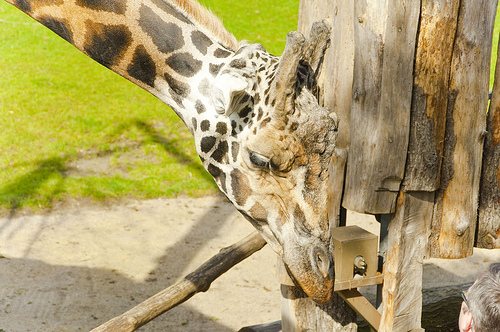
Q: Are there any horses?
A: No, there are no horses.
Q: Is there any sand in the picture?
A: Yes, there is sand.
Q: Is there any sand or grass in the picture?
A: Yes, there is sand.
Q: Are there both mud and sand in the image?
A: No, there is sand but no mud.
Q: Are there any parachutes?
A: No, there are no parachutes.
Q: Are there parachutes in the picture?
A: No, there are no parachutes.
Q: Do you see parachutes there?
A: No, there are no parachutes.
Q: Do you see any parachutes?
A: No, there are no parachutes.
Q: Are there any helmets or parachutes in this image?
A: No, there are no parachutes or helmets.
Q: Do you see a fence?
A: Yes, there is a fence.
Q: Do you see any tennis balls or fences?
A: Yes, there is a fence.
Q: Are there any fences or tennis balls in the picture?
A: Yes, there is a fence.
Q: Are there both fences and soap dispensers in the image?
A: No, there is a fence but no soap dispensers.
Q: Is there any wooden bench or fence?
A: Yes, there is a wood fence.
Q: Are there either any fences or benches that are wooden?
A: Yes, the fence is wooden.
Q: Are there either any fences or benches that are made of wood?
A: Yes, the fence is made of wood.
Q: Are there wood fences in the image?
A: Yes, there is a wood fence.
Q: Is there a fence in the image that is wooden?
A: Yes, there is a fence that is wooden.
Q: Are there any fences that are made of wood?
A: Yes, there is a fence that is made of wood.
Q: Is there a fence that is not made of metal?
A: Yes, there is a fence that is made of wood.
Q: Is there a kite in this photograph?
A: No, there are no kites.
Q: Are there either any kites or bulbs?
A: No, there are no kites or bulbs.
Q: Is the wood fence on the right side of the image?
A: Yes, the fence is on the right of the image.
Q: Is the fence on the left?
A: No, the fence is on the right of the image.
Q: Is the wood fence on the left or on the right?
A: The fence is on the right of the image.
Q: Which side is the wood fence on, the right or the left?
A: The fence is on the right of the image.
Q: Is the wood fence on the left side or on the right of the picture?
A: The fence is on the right of the image.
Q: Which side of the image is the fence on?
A: The fence is on the right of the image.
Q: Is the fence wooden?
A: Yes, the fence is wooden.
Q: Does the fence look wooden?
A: Yes, the fence is wooden.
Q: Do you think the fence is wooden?
A: Yes, the fence is wooden.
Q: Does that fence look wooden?
A: Yes, the fence is wooden.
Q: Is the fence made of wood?
A: Yes, the fence is made of wood.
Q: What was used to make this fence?
A: The fence is made of wood.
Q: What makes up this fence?
A: The fence is made of wood.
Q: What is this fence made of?
A: The fence is made of wood.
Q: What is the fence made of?
A: The fence is made of wood.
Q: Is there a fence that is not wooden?
A: No, there is a fence but it is wooden.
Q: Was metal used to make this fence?
A: No, the fence is made of wood.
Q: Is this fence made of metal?
A: No, the fence is made of wood.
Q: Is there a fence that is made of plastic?
A: No, there is a fence but it is made of wood.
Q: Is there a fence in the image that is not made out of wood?
A: No, there is a fence but it is made of wood.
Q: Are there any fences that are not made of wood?
A: No, there is a fence but it is made of wood.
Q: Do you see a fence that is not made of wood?
A: No, there is a fence but it is made of wood.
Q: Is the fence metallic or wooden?
A: The fence is wooden.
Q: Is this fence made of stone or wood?
A: The fence is made of wood.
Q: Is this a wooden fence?
A: Yes, this is a wooden fence.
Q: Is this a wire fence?
A: No, this is a wooden fence.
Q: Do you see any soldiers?
A: No, there are no soldiers.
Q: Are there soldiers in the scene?
A: No, there are no soldiers.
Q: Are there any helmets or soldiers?
A: No, there are no soldiers or helmets.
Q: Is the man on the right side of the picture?
A: Yes, the man is on the right of the image.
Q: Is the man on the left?
A: No, the man is on the right of the image.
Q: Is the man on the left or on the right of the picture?
A: The man is on the right of the image.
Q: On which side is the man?
A: The man is on the right of the image.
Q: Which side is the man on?
A: The man is on the right of the image.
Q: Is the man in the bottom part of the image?
A: Yes, the man is in the bottom of the image.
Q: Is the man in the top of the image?
A: No, the man is in the bottom of the image.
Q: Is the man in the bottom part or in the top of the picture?
A: The man is in the bottom of the image.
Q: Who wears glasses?
A: The man wears glasses.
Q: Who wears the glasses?
A: The man wears glasses.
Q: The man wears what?
A: The man wears glasses.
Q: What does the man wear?
A: The man wears glasses.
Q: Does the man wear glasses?
A: Yes, the man wears glasses.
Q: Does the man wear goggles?
A: No, the man wears glasses.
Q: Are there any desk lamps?
A: No, there are no desk lamps.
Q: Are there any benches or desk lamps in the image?
A: No, there are no desk lamps or benches.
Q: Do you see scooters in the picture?
A: No, there are no scooters.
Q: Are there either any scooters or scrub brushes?
A: No, there are no scooters or scrub brushes.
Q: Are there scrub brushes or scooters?
A: No, there are no scooters or scrub brushes.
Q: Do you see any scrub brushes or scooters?
A: No, there are no scooters or scrub brushes.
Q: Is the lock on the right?
A: Yes, the lock is on the right of the image.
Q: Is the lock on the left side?
A: No, the lock is on the right of the image.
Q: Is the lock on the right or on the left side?
A: The lock is on the right of the image.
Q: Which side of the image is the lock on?
A: The lock is on the right of the image.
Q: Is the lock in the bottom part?
A: Yes, the lock is in the bottom of the image.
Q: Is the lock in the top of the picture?
A: No, the lock is in the bottom of the image.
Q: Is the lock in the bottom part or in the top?
A: The lock is in the bottom of the image.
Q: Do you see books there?
A: No, there are no books.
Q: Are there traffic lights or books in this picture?
A: No, there are no books or traffic lights.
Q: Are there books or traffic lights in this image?
A: No, there are no books or traffic lights.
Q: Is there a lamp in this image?
A: No, there are no lamps.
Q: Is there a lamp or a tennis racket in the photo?
A: No, there are no lamps or rackets.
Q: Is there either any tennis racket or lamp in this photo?
A: No, there are no lamps or rackets.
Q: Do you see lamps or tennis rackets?
A: No, there are no lamps or tennis rackets.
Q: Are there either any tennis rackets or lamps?
A: No, there are no lamps or tennis rackets.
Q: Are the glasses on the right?
A: Yes, the glasses are on the right of the image.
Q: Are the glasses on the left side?
A: No, the glasses are on the right of the image.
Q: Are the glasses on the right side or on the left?
A: The glasses are on the right of the image.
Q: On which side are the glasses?
A: The glasses are on the right of the image.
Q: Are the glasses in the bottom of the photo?
A: Yes, the glasses are in the bottom of the image.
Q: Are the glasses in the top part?
A: No, the glasses are in the bottom of the image.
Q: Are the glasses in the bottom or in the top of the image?
A: The glasses are in the bottom of the image.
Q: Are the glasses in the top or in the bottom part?
A: The glasses are in the bottom of the image.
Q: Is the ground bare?
A: Yes, the ground is bare.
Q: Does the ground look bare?
A: Yes, the ground is bare.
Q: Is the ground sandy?
A: No, the ground is bare.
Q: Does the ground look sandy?
A: No, the ground is bare.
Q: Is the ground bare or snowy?
A: The ground is bare.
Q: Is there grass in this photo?
A: Yes, there is grass.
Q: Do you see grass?
A: Yes, there is grass.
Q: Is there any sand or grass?
A: Yes, there is grass.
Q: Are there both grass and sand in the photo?
A: Yes, there are both grass and sand.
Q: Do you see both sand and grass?
A: Yes, there are both grass and sand.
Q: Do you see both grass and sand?
A: Yes, there are both grass and sand.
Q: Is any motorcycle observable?
A: No, there are no motorcycles.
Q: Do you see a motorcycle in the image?
A: No, there are no motorcycles.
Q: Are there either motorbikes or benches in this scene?
A: No, there are no motorbikes or benches.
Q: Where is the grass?
A: The grass is on the ground.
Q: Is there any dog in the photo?
A: No, there are no dogs.